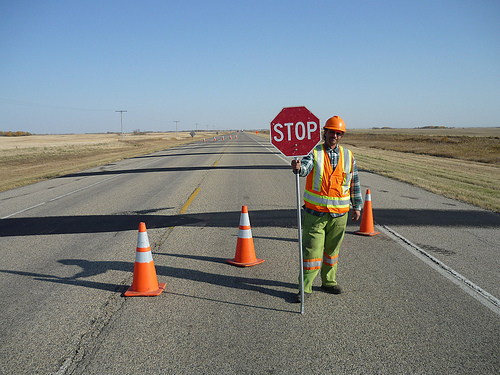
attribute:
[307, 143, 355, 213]
vest — orange 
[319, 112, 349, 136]
helmet — orange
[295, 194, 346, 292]
pants — green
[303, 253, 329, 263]
stripe — orange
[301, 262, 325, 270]
stripe — orange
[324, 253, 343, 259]
stripe — orange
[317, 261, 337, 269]
stripe — orange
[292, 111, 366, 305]
man — safety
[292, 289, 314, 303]
sneaker — black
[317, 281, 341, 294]
sneaker — black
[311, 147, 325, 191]
patch — gray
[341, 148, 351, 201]
patch — gray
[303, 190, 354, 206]
patch — gray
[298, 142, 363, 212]
shirt — blue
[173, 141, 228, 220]
line — yellow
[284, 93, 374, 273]
man — SHADOW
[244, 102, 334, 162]
sign — STOP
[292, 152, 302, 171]
hand — MAN'S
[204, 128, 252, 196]
street — OPEN, EMPTY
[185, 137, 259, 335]
street — VANISHING, POINT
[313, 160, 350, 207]
vest — ORANGE, REFLECTER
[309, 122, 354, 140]
hat — ORANGE, HARD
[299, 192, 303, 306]
pole — METAL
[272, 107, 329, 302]
sign — STOP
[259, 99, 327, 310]
sign — STOP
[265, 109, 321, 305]
sign — STOP, POLE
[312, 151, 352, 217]
vest — SAFETY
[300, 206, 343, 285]
pants — SAFETY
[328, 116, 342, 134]
helmet — HAT, HARD, ORANGE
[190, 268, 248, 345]
road — SHADOWS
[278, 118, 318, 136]
lettering — WHITE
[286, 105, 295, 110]
background — RED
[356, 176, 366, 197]
shirt — PLAID, LONG SLEEVE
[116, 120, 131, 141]
pole — UTILITY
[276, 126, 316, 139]
letter — WHITE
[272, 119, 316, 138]
letter — WHITE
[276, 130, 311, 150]
letter — WHITE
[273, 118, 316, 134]
letter — WHITE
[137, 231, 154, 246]
stripe — WHITE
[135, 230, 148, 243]
stripe — WHITE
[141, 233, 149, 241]
stripe — WHITE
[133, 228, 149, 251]
stripe — WHITE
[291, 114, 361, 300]
man — orange, hard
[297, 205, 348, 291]
green pants — orange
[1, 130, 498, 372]
road — long , straignt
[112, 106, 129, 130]
pole — electrical